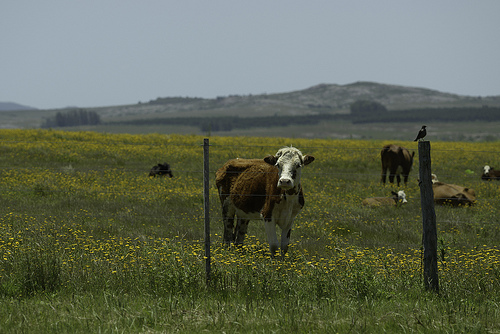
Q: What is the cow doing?
A: Standing.